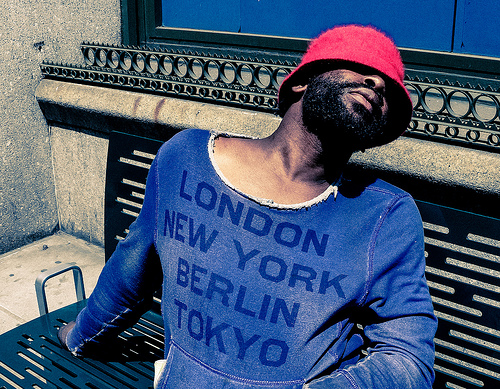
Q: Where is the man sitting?
A: On a bench.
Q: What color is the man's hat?
A: Red.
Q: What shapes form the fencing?
A: Circles.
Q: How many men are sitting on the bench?
A: One.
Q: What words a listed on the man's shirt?
A: London, New York, Berlin, Tokyo.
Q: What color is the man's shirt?
A: Blue.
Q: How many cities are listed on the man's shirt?
A: Four.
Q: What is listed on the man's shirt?
A: City names.